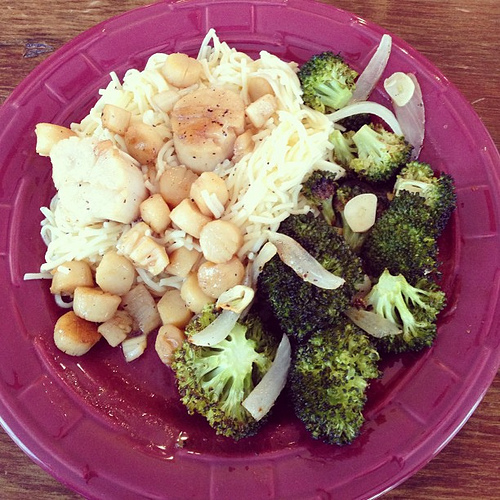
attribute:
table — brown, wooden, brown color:
[1, 1, 500, 497]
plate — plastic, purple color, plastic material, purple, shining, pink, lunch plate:
[1, 1, 500, 500]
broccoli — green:
[171, 307, 278, 442]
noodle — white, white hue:
[43, 232, 109, 272]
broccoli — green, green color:
[348, 123, 415, 183]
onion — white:
[251, 230, 346, 290]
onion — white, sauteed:
[241, 332, 294, 424]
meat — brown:
[170, 88, 246, 174]